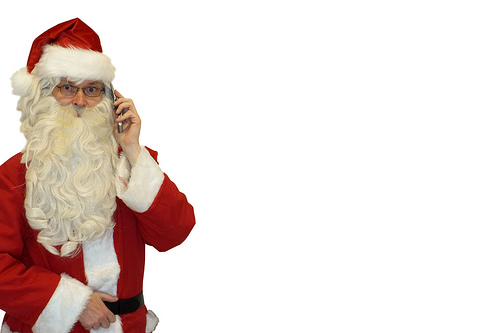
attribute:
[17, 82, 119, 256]
beard — white, long, curly, yellowed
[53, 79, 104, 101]
glasses — black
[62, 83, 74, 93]
eye — blue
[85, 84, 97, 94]
eye — blue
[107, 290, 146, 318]
belt — black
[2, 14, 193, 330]
clothes — red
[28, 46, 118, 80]
trim — white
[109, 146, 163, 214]
trim — white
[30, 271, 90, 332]
trim — white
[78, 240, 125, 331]
trim — white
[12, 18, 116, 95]
hat — red, white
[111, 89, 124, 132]
cell phone — small, silver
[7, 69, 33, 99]
ball — white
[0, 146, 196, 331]
jacket — red, white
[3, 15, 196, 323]
santa — red, white